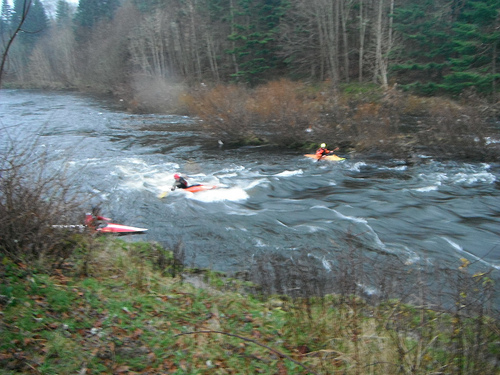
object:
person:
[170, 174, 186, 192]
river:
[0, 87, 500, 316]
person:
[315, 142, 334, 164]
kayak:
[300, 153, 345, 161]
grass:
[179, 81, 499, 164]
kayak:
[48, 221, 149, 234]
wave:
[150, 155, 305, 216]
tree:
[271, 0, 395, 91]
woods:
[0, 0, 499, 162]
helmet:
[319, 142, 327, 148]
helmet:
[173, 173, 181, 181]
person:
[84, 206, 111, 230]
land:
[0, 215, 499, 375]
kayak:
[154, 183, 220, 200]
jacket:
[177, 178, 189, 189]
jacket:
[317, 148, 329, 159]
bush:
[1, 108, 108, 274]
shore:
[1, 203, 500, 375]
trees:
[0, 0, 497, 89]